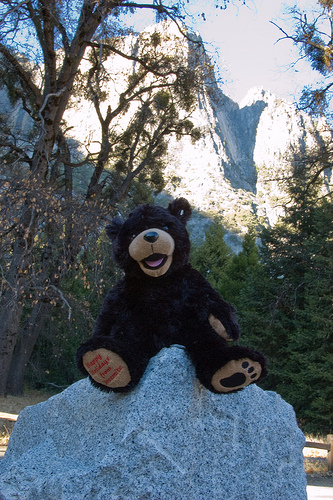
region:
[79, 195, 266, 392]
teddy bear on top of rock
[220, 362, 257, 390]
paw on teddy bear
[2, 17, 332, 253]
mountains behind teddy bear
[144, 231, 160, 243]
black nose eon teddy bear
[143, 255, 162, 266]
pink tongue on teddy bear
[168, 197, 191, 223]
brown ear on teddy bear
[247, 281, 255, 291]
a green leaf on a tree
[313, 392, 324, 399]
a green leaf on a tree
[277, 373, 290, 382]
a green leaf on a tree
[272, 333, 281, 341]
a green leaf on a tree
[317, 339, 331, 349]
a green leaf on a tree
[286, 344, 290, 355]
a green leaf on a tree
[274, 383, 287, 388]
a green leaf on a tree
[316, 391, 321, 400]
a green leaf on a tree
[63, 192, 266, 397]
Teddy bear sitting on a rock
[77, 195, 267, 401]
Teddy bear sitting on a rock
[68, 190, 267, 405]
Teddy bear sitting on a rock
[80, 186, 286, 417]
Teddy bear sitting on a rock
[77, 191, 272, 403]
Teddy bear sitting on a rock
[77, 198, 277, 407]
Teddy bear sitting on a rock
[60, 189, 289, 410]
Teddy bear sitting on a rock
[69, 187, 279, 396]
Teddy bear sitting on a rock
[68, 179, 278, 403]
Teddy bear sitting on a rock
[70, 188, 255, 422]
teddy bear is brown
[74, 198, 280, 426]
teddy bear is brown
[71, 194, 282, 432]
teddy bear is brown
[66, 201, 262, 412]
teddy bear is brown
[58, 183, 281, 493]
teddy bear is sitting on a rock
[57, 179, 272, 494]
teddy bear is sitting on a rock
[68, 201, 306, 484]
teddy bear is sitting on a rock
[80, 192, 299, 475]
teddy bear is sitting on a rock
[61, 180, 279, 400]
this is a teddy bear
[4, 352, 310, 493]
this is a big rock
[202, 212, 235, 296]
this is a tree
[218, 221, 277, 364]
this is a tree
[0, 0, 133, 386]
this is a tree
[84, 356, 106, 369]
a word on the sole of a teddy bear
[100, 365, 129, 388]
a word on the sole of a teddy bear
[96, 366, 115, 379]
a word on the sole of a teddy bear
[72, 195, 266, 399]
stuffed bear sitting on rock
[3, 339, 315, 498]
blue gray granite rock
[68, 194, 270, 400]
toy black bear on rock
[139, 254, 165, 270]
pink tongue of toy bear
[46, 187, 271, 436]
a teddy bear on a rock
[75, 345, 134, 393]
bottom of leg is brown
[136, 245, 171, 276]
the mouth is open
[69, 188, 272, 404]
the bear is large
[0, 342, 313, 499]
the stone is gray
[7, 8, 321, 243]
the sun iluminted the mountain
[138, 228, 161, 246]
the nose is brown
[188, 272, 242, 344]
the arm of a plush bear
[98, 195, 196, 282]
the face is light brown and dark brown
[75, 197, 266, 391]
black teddy bear with brown paws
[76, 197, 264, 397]
black teddy bear with pink tongue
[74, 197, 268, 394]
black teddy bear with black nose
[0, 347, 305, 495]
huge boulder sitting under teddy bear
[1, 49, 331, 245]
huge mountains in the background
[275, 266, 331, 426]
tall green tree growing in front of mountains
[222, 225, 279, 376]
tall green tree growing in front of mountains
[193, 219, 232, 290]
tall green tree growing in front of mountains